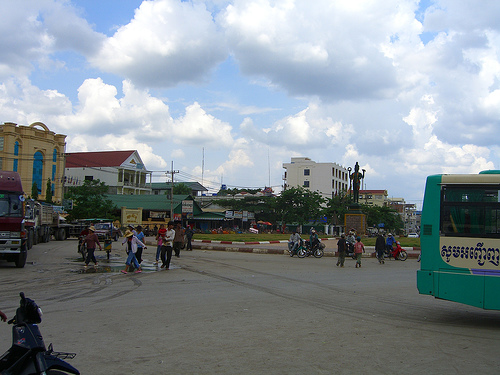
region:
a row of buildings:
[281, 155, 419, 235]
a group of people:
[70, 215, 190, 270]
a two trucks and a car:
[0, 170, 120, 265]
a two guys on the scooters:
[285, 225, 320, 255]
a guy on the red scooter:
[380, 230, 400, 260]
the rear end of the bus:
[410, 165, 490, 305]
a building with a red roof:
[65, 147, 150, 189]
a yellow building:
[0, 120, 65, 200]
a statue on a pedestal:
[340, 160, 370, 236]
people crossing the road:
[1, 222, 226, 270]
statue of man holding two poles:
[346, 160, 366, 210]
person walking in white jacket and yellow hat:
[122, 227, 147, 277]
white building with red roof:
[65, 148, 151, 195]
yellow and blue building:
[1, 120, 66, 207]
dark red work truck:
[0, 169, 28, 266]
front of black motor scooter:
[3, 287, 80, 373]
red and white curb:
[189, 237, 333, 248]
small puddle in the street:
[70, 260, 172, 274]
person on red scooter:
[382, 233, 397, 255]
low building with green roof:
[67, 188, 199, 225]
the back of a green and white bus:
[415, 168, 499, 310]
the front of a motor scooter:
[2, 291, 82, 373]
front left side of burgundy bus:
[0, 170, 29, 268]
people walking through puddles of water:
[76, 220, 176, 275]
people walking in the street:
[77, 217, 194, 277]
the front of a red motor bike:
[390, 240, 408, 260]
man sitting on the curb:
[286, 228, 301, 255]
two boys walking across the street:
[335, 233, 367, 269]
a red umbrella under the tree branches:
[255, 218, 271, 234]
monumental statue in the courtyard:
[341, 160, 364, 235]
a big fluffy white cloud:
[87, 1, 233, 86]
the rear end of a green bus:
[415, 168, 499, 308]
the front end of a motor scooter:
[0, 291, 80, 373]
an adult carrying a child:
[155, 221, 175, 269]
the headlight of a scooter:
[32, 304, 44, 322]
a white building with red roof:
[61, 150, 147, 195]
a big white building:
[282, 157, 349, 204]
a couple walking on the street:
[334, 235, 365, 266]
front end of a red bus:
[0, 174, 27, 266]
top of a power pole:
[165, 160, 181, 194]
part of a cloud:
[266, 32, 299, 68]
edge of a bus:
[416, 264, 430, 307]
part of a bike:
[13, 329, 38, 360]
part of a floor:
[227, 324, 264, 371]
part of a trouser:
[163, 247, 179, 266]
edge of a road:
[242, 248, 265, 256]